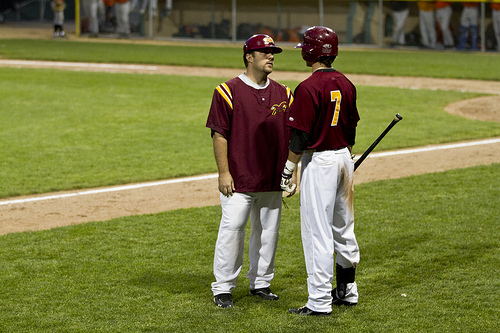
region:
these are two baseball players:
[191, 27, 369, 300]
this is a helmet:
[310, 28, 337, 53]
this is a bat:
[365, 104, 402, 159]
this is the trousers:
[305, 161, 349, 258]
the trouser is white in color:
[305, 174, 348, 235]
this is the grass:
[99, 225, 184, 317]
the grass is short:
[83, 241, 195, 322]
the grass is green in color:
[74, 231, 190, 321]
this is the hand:
[208, 140, 237, 192]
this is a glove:
[276, 160, 301, 193]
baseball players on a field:
[195, 15, 424, 321]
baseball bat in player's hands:
[361, 104, 403, 181]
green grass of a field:
[11, 70, 201, 167]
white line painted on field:
[10, 185, 147, 210]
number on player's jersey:
[321, 84, 351, 142]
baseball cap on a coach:
[241, 26, 294, 54]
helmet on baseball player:
[289, 20, 346, 54]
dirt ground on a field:
[460, 95, 497, 124]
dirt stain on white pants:
[342, 171, 359, 217]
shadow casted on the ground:
[364, 224, 493, 294]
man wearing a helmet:
[301, 17, 406, 313]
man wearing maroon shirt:
[291, 20, 396, 325]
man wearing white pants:
[290, 15, 387, 320]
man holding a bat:
[303, 16, 413, 321]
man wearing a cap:
[185, 21, 296, 301]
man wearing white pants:
[185, 20, 285, 315]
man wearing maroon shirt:
[201, 30, 281, 305]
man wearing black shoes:
[190, 30, 281, 318]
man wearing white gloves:
[275, 20, 370, 328]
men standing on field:
[175, 23, 405, 328]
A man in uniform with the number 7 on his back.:
[279, 26, 359, 312]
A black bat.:
[356, 113, 403, 170]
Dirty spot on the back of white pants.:
[335, 163, 354, 210]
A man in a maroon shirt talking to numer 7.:
[206, 33, 293, 305]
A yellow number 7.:
[327, 88, 341, 125]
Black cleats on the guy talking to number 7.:
[211, 286, 278, 307]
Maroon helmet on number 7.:
[293, 25, 338, 64]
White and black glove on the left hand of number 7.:
[280, 173, 297, 196]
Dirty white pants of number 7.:
[292, 147, 357, 312]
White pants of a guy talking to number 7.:
[211, 188, 282, 293]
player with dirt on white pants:
[279, 21, 373, 315]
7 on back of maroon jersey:
[321, 82, 350, 131]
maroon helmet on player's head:
[289, 16, 338, 76]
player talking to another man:
[208, 21, 289, 307]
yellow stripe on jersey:
[218, 84, 235, 106]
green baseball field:
[4, 37, 496, 332]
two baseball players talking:
[202, 18, 365, 316]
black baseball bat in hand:
[339, 109, 399, 179]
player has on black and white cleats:
[205, 287, 282, 312]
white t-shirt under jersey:
[240, 71, 275, 99]